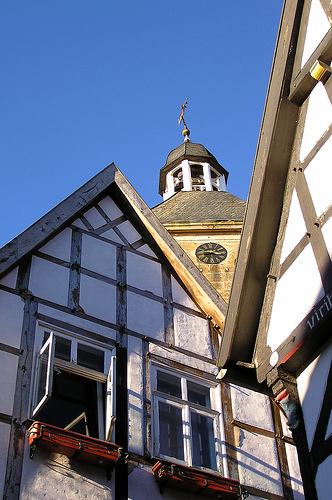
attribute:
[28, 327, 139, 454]
window — black, open, large, close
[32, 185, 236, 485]
building — white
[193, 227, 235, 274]
clock — black, round, roman, small, tall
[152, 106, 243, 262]
tower — brown, white, stone, close, huge, tall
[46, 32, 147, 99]
sky — clear, blue, sunny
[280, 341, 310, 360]
paint — red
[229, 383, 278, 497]
tiles — white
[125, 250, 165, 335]
tiles — white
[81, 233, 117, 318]
tiles — white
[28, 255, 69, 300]
tiles — white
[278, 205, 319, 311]
tiles — white